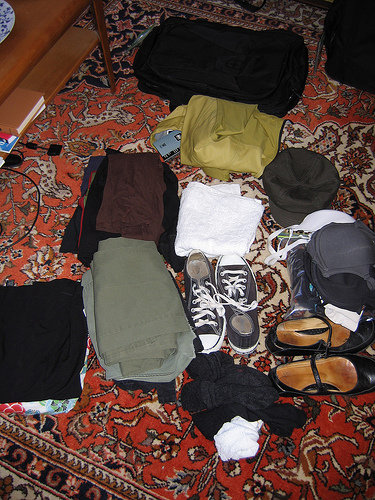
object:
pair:
[183, 248, 261, 353]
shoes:
[215, 249, 261, 355]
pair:
[264, 316, 374, 397]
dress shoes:
[267, 354, 375, 397]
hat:
[262, 147, 340, 228]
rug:
[0, 1, 375, 499]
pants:
[89, 236, 191, 377]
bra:
[305, 219, 374, 291]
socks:
[181, 380, 280, 410]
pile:
[180, 350, 307, 461]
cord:
[0, 165, 41, 252]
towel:
[174, 181, 265, 260]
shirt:
[96, 152, 168, 243]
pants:
[81, 237, 198, 384]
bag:
[132, 16, 309, 119]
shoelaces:
[190, 282, 226, 329]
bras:
[304, 249, 375, 317]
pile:
[263, 209, 373, 316]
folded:
[0, 278, 86, 406]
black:
[0, 278, 88, 403]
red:
[0, 1, 375, 499]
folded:
[174, 181, 265, 259]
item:
[174, 179, 265, 259]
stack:
[58, 147, 179, 270]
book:
[0, 89, 47, 135]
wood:
[0, 0, 116, 168]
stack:
[80, 237, 204, 405]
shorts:
[0, 278, 89, 404]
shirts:
[59, 148, 178, 269]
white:
[201, 337, 216, 344]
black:
[184, 350, 235, 381]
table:
[0, 0, 117, 169]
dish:
[0, 0, 15, 45]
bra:
[263, 208, 356, 266]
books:
[0, 104, 46, 145]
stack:
[1, 88, 48, 155]